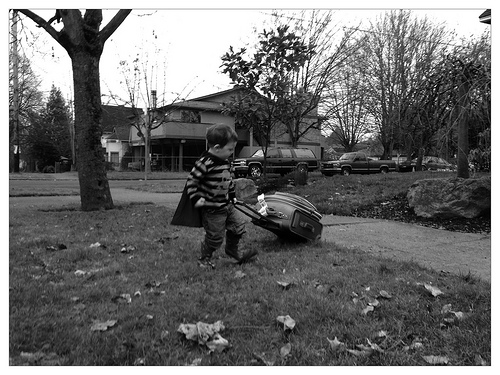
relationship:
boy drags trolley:
[196, 117, 237, 255] [230, 181, 328, 248]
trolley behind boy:
[246, 172, 340, 255] [196, 117, 237, 255]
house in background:
[176, 82, 311, 166] [44, 59, 496, 178]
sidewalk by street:
[30, 172, 78, 206] [31, 140, 208, 190]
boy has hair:
[196, 117, 237, 255] [196, 121, 248, 146]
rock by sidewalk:
[408, 169, 499, 243] [30, 172, 78, 206]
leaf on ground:
[175, 303, 223, 354] [52, 257, 456, 349]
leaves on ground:
[113, 285, 323, 372] [52, 257, 456, 349]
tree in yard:
[57, 13, 141, 244] [8, 99, 174, 329]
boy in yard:
[196, 117, 237, 255] [8, 99, 174, 329]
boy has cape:
[196, 117, 237, 255] [145, 174, 244, 276]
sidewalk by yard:
[30, 172, 78, 206] [8, 99, 174, 329]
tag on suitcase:
[249, 197, 269, 216] [264, 196, 328, 237]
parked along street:
[256, 138, 468, 221] [31, 140, 208, 190]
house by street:
[176, 82, 311, 166] [31, 140, 208, 190]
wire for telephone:
[270, 12, 477, 60] [224, 17, 456, 137]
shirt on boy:
[195, 161, 235, 202] [196, 117, 237, 255]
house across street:
[176, 82, 311, 166] [31, 140, 208, 190]